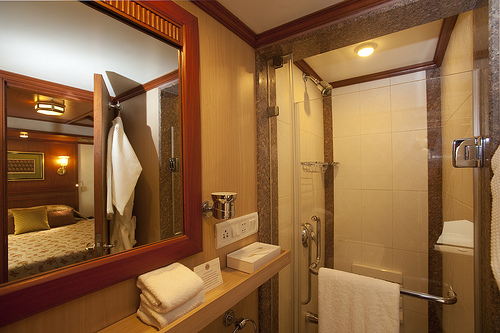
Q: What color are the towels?
A: White.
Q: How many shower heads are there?
A: One.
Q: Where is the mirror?
A: On the wall.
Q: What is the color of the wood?
A: Brown.